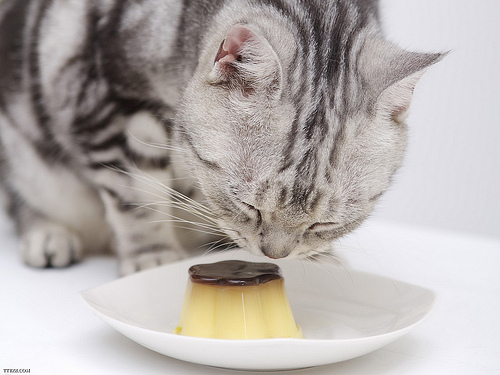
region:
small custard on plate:
[154, 221, 305, 341]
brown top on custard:
[186, 258, 276, 307]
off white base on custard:
[167, 295, 287, 349]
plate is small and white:
[128, 246, 398, 374]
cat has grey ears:
[216, 38, 411, 108]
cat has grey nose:
[254, 231, 308, 258]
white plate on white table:
[86, 229, 407, 367]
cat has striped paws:
[111, 156, 199, 263]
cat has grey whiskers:
[120, 171, 240, 253]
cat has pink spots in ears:
[201, 12, 278, 85]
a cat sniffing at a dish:
[0, 4, 465, 268]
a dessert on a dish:
[170, 252, 300, 345]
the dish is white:
[78, 242, 449, 365]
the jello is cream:
[177, 259, 301, 342]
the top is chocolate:
[179, 259, 287, 288]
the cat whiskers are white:
[109, 112, 395, 281]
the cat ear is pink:
[200, 23, 287, 98]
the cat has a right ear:
[359, 23, 454, 129]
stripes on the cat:
[265, 0, 371, 209]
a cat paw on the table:
[11, 194, 86, 266]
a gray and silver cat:
[14, 2, 441, 277]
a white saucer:
[89, 253, 441, 367]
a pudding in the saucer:
[175, 265, 315, 335]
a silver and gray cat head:
[171, 18, 465, 254]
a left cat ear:
[361, 38, 454, 128]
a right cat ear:
[209, 18, 308, 98]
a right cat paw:
[117, 165, 190, 277]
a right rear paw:
[18, 206, 100, 268]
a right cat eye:
[226, 183, 282, 228]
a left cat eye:
[304, 210, 344, 243]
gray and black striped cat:
[3, 0, 448, 251]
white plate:
[81, 237, 434, 368]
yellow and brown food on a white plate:
[178, 258, 302, 361]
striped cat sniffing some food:
[167, 0, 447, 260]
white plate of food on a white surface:
[5, 269, 482, 371]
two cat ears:
[211, 18, 450, 117]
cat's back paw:
[18, 221, 83, 268]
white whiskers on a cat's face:
[101, 161, 247, 246]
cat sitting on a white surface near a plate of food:
[3, 2, 448, 367]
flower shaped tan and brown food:
[181, 260, 305, 338]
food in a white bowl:
[77, 249, 439, 374]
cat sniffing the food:
[178, 23, 452, 315]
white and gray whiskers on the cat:
[108, 125, 390, 261]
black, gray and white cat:
[1, 0, 451, 275]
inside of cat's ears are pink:
[205, 20, 281, 105]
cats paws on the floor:
[20, 225, 185, 275]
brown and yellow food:
[175, 257, 300, 334]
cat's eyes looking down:
[230, 185, 340, 230]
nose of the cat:
[255, 211, 305, 256]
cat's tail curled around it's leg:
[0, 111, 122, 251]